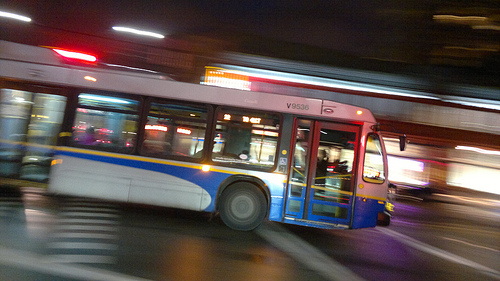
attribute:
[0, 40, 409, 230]
bus — white, city bus, blue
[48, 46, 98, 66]
light — glowing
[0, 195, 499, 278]
lines — painted, white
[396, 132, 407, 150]
mirror — side view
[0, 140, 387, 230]
trim — blue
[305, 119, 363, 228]
door — closed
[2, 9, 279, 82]
lights — lit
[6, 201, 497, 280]
road — painted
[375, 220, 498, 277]
line — white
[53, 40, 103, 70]
light — red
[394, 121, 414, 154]
mirror — black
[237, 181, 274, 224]
part of a wheel — pictured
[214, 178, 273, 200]
part of a wheel — pictured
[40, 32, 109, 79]
light above bus — red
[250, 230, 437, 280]
lines on the road — white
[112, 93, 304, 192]
glass — transparent